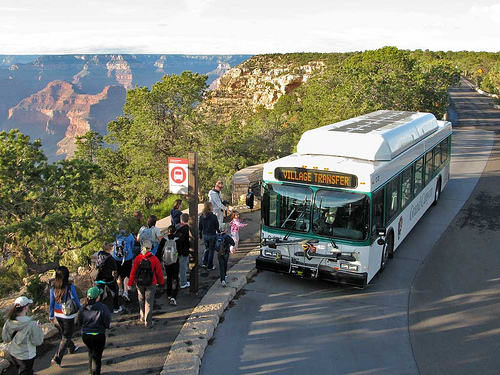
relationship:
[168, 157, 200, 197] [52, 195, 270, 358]
sign for bus stop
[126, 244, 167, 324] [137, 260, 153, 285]
woman wearing a backpack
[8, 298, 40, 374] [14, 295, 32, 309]
woman wearing white cap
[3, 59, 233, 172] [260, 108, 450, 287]
mountains behind bus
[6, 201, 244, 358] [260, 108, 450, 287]
people waiting for bus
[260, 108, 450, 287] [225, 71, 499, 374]
bus on side of road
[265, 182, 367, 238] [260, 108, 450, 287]
windshield on bus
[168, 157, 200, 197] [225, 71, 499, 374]
sign next to road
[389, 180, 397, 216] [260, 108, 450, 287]
window on side of bus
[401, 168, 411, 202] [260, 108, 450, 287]
window on side of bus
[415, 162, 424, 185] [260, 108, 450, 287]
window on side of bus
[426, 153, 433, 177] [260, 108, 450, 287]
window on side of bus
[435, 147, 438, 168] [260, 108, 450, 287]
window on side of bus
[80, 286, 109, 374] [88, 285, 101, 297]
person wearing green cap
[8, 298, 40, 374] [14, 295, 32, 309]
person wearing white cap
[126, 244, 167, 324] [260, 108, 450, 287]
woman walking toward bus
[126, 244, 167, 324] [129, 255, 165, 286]
woman wearing red jacket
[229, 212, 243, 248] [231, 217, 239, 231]
girl in pink shirt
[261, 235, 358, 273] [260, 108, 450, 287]
bike rack on bus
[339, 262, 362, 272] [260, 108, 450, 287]
headlight on bus